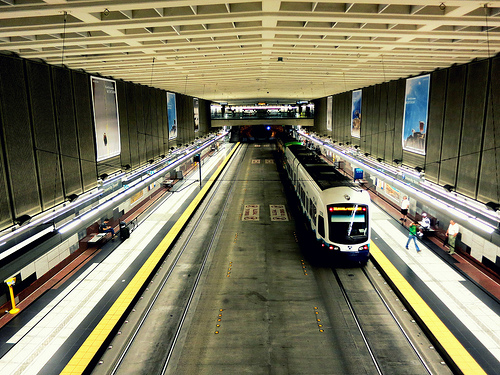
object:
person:
[445, 219, 460, 255]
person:
[399, 196, 411, 223]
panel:
[50, 63, 84, 201]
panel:
[71, 70, 98, 193]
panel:
[0, 54, 43, 226]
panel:
[25, 58, 65, 211]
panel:
[452, 59, 488, 200]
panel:
[422, 66, 448, 185]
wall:
[307, 55, 500, 205]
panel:
[124, 81, 139, 169]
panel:
[149, 86, 160, 158]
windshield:
[326, 202, 369, 245]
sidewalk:
[367, 197, 500, 375]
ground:
[209, 141, 307, 225]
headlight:
[333, 246, 338, 250]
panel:
[115, 79, 131, 171]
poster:
[401, 73, 431, 155]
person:
[405, 221, 422, 253]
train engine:
[320, 186, 373, 269]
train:
[272, 127, 372, 268]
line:
[369, 228, 500, 370]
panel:
[156, 87, 165, 156]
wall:
[0, 47, 206, 223]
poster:
[90, 75, 122, 162]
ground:
[219, 222, 308, 374]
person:
[416, 212, 430, 237]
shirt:
[420, 217, 430, 230]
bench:
[414, 209, 442, 236]